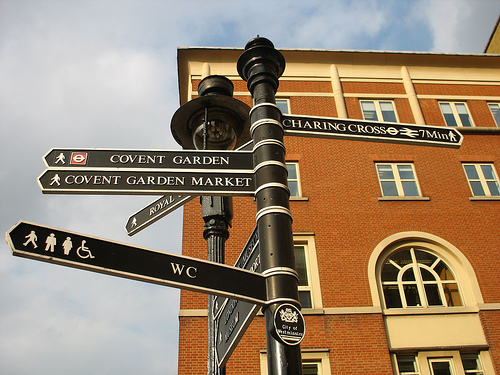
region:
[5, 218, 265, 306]
sign that shows where the bathrooms are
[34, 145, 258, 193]
sign that shows direction to Covent Garden and market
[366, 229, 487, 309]
arched window in brick building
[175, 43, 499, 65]
roof soffit and edge of shingles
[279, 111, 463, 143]
sign showing direction to Charing Cross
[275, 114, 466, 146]
sign showing how long it will take to walk to Charing Cross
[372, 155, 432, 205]
window installed in brick building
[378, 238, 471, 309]
mullions in arched window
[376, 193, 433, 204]
concrete ledge of window sill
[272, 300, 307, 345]
city marker on pole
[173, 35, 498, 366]
large red brick building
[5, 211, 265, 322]
black street sign with symbols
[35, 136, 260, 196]
two black streets signs attached to post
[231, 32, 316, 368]
black post holding street signs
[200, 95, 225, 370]
black light post with street sign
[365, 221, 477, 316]
arched window on building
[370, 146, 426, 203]
window on the brick building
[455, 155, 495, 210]
window on the large brick building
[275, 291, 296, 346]
circle sign on the side of the pole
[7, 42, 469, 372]
large black post with street signs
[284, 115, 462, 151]
charing cross street sign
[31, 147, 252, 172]
covent garden street sign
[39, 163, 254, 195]
sign to covent garden market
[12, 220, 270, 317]
sign guiding you to wc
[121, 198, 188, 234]
partial sign to royal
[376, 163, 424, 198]
4 paned glass window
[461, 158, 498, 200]
4 paned glass window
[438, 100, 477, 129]
2 paned glass window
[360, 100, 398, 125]
2 paned glass window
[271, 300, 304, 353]
white letter telling what city you are in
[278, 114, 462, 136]
black sign on pole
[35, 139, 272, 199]
two black signs touching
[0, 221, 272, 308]
black sign on pole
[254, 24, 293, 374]
long black pole with signs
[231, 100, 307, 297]
round metal holders on black pole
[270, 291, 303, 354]
circle sign on front of pole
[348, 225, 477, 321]
front archway on building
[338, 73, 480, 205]
windows on front of building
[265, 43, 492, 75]
white colored roof of building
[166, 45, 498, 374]
large brick building with windows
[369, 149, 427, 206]
Brick building with a window.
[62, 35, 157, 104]
Many clouds in the sky.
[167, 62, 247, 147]
Top of tall street light.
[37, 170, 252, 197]
Arrow for directions to Covent Garden Market.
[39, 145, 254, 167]
The way to Covent Garden.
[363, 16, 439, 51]
Small patch of almost clear sky.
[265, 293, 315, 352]
Small sign on pole.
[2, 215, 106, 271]
WC is capable for someone in a wheelchair.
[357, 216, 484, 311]
Arched window in the middle of the building.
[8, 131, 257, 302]
The sign are very helpful.